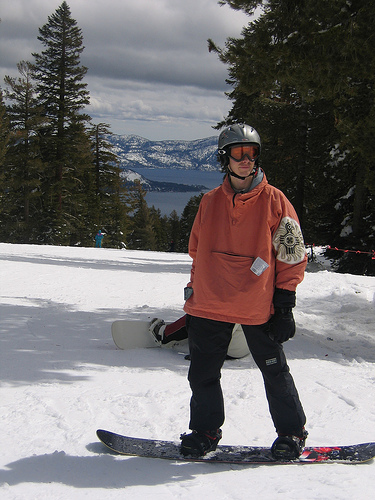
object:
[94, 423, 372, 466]
snowboard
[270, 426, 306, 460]
boot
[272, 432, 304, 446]
binder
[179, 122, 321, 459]
man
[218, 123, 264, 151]
helmet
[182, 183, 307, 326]
jacket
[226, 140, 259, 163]
goggles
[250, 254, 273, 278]
ticket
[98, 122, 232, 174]
mountains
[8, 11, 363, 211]
distance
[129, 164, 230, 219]
lake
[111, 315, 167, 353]
snowboard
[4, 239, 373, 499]
snow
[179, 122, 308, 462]
person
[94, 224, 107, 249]
person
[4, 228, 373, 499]
hill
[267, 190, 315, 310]
sleeve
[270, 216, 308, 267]
graphic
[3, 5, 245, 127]
clouds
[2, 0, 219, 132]
sky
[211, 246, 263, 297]
pocket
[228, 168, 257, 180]
chin strap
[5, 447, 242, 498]
shadow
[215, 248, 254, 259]
zipper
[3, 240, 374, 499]
ground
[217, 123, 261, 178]
head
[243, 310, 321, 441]
leg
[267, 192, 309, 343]
arm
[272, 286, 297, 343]
glove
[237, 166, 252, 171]
mouth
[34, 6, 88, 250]
tree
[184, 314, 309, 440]
pants